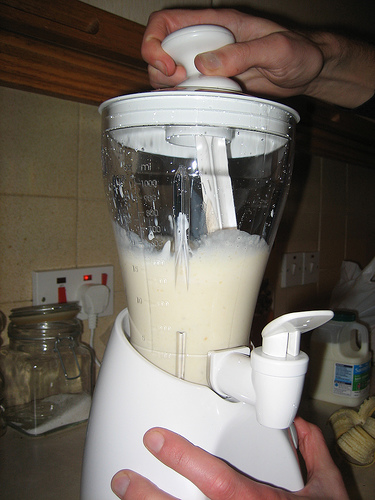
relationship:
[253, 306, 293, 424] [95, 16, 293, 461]
spout attached to blender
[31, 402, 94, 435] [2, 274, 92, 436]
powder inside of canister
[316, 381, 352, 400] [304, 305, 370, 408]
milk inside of bottle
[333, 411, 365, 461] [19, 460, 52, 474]
banana peel on top of counter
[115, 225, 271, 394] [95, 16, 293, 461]
drink inside of blender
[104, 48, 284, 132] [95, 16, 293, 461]
top of blender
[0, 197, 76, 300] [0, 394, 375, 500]
tile on back of counter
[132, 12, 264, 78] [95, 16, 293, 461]
fingers holding blender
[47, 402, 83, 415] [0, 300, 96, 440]
powder inside of canister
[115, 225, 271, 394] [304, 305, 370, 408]
drink inside of bottle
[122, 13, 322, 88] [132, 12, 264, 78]
hand curled around knob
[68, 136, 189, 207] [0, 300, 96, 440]
splatters on top of canister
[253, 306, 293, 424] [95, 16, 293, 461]
spout on front of blender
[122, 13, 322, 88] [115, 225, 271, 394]
hand holding drink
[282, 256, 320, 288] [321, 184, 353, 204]
light switches attached to wall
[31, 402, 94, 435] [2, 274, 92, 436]
powder inside of jar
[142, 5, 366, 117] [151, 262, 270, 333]
person making snack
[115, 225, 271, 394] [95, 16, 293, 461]
drink inside of mixer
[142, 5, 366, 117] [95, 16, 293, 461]
person using blender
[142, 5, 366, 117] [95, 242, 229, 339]
man preparing drink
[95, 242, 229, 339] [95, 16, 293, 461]
drink inside of blender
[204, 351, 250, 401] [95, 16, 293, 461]
spigot attached to blender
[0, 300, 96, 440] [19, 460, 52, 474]
canister on top of counter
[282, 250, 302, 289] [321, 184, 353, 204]
light switches attached to wall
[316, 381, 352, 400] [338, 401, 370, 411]
milk inside of bottle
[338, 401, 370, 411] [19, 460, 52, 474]
bottle on top of counter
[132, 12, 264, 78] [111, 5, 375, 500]
right hand of person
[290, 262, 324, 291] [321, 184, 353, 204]
switches attached to wall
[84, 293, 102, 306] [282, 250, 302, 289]
plug inside of light switches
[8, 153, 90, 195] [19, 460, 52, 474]
tile behind counter